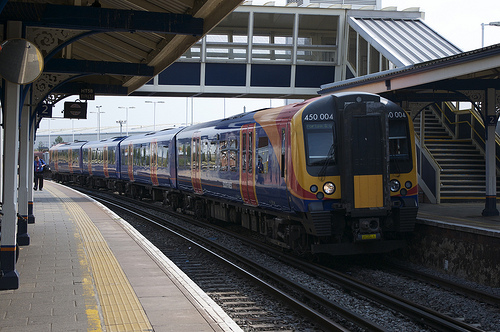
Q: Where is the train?
A: In the station.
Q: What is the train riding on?
A: Tracks.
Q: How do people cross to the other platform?
A: Overpass.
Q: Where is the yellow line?
A: Platform.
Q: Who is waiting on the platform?
A: Passnger.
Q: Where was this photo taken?
A: Train station.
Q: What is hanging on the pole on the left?
A: Mirror.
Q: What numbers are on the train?
A: 450004.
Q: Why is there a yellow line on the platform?
A: To remind people to stay back.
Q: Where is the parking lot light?
A: Top right.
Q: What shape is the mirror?
A: Round.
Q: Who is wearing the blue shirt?
A: The man.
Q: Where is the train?
A: On the right track.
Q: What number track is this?
A: 2.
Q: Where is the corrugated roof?
A: Over stairs.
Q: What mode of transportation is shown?
A: Train.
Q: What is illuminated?
A: Headlight on the left.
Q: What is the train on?
A: Tracks.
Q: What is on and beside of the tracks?
A: Gravel.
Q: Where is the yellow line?
A: On the walkway.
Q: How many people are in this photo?
A: One.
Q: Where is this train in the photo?
A: Train Station.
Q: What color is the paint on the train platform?
A: Yellow.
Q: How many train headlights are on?
A: One.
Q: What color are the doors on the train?
A: Red and Yellow.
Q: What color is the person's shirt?
A: Blue.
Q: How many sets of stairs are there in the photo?
A: One.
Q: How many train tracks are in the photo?
A: Two.